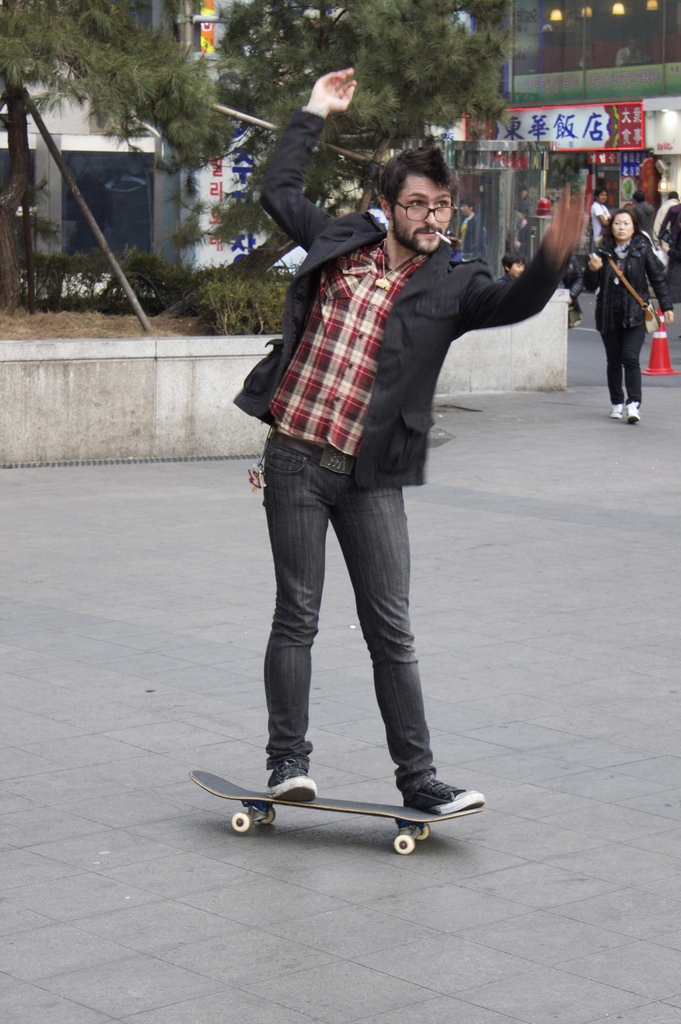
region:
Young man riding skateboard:
[188, 65, 590, 855]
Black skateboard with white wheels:
[185, 767, 486, 854]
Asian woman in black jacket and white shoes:
[583, 206, 675, 423]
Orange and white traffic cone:
[640, 306, 679, 377]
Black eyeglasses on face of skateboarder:
[384, 199, 460, 225]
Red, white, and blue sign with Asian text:
[463, 100, 647, 153]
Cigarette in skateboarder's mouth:
[433, 228, 452, 245]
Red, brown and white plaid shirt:
[263, 240, 435, 458]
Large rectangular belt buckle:
[317, 443, 356, 478]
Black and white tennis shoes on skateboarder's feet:
[267, 754, 486, 818]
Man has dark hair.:
[376, 140, 454, 192]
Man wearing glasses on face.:
[397, 193, 468, 223]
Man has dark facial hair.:
[393, 216, 457, 264]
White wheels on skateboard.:
[220, 813, 432, 851]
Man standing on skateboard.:
[218, 759, 458, 856]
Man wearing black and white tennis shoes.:
[266, 761, 473, 811]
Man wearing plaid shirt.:
[315, 268, 392, 453]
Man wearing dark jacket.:
[229, 95, 543, 472]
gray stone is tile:
[122, 721, 231, 755]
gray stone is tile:
[188, 870, 346, 935]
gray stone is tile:
[380, 880, 531, 932]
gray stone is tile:
[468, 903, 626, 964]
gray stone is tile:
[36, 948, 225, 1022]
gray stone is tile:
[83, 896, 249, 954]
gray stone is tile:
[18, 862, 156, 920]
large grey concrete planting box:
[0, 287, 572, 470]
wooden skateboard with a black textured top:
[189, 767, 485, 853]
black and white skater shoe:
[404, 774, 487, 814]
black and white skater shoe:
[268, 761, 320, 802]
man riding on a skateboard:
[230, 65, 589, 816]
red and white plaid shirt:
[265, 242, 429, 456]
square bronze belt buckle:
[317, 447, 358, 477]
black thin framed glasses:
[385, 192, 457, 226]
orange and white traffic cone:
[641, 305, 676, 376]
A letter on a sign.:
[578, 108, 607, 143]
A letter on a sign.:
[550, 113, 582, 141]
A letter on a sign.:
[525, 108, 551, 141]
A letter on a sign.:
[619, 107, 632, 125]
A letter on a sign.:
[621, 127, 633, 146]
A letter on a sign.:
[209, 181, 223, 198]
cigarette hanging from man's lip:
[436, 230, 452, 242]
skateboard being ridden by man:
[191, 769, 485, 854]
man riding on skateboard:
[233, 65, 587, 816]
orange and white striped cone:
[640, 307, 677, 375]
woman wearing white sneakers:
[581, 209, 672, 422]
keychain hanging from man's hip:
[247, 443, 270, 495]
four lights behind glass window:
[550, 0, 660, 21]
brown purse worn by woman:
[608, 257, 662, 332]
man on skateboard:
[187, 65, 589, 854]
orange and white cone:
[642, 302, 679, 377]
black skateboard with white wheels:
[185, 767, 482, 852]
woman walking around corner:
[584, 205, 676, 422]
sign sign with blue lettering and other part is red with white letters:
[460, 99, 645, 154]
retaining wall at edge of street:
[1, 285, 574, 462]